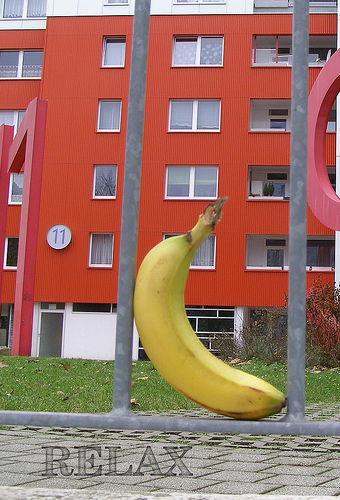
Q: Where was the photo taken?
A: Outside of a fence.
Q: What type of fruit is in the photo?
A: A banana.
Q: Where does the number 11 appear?
A: On the front of the building.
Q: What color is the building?
A: Orange.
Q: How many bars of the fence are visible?
A: Two.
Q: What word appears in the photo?
A: Relax.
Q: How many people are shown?
A: None.